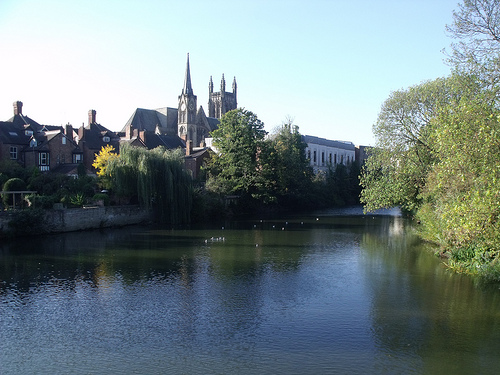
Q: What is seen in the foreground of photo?
A: Water.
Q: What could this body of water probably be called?
A: Canal.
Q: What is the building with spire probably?
A: Church.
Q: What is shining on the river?
A: Sun.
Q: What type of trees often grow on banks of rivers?
A: Cypress.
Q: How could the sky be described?
A: Clear.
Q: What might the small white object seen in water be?
A: Ducks.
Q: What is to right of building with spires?
A: White building.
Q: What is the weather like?
A: Mostly sunny.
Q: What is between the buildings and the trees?
A: A river.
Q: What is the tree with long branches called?
A: Willow.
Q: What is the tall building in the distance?
A: A chapel.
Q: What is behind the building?
A: A brick building.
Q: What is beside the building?
A: A yellow tree.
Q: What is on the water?
A: White ducks.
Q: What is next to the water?
A: Green trees.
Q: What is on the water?
A: Small ripples.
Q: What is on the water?
A: Shadows of buildings.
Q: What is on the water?
A: Lots of white ducks.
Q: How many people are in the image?
A: 0.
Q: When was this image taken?
A: In the daytime.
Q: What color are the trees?
A: Green.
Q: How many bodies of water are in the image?
A: 1.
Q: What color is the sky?
A: Blue.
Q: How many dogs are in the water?
A: 0.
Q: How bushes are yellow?
A: 1.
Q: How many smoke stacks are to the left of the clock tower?
A: 2.